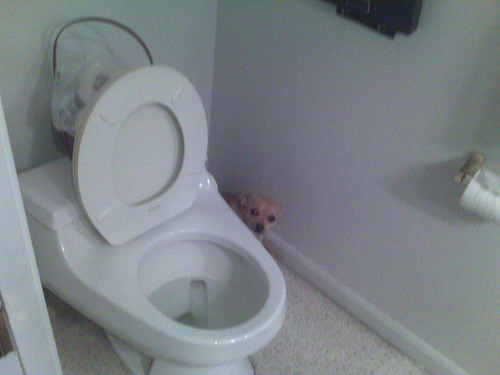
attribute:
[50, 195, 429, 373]
carpet — white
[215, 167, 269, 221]
coat — dog's, light, brown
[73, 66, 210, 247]
seat — up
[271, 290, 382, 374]
carpet — light, tan, colored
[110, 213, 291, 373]
toilet — white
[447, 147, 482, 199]
holder — toilet, paper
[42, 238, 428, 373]
carpet — white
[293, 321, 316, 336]
carpet — white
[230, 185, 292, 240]
dog — small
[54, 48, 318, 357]
seat — up, toilet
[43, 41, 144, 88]
toilet paper — roll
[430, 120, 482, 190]
holder — toilet paper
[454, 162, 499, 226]
roll — toilet, paper